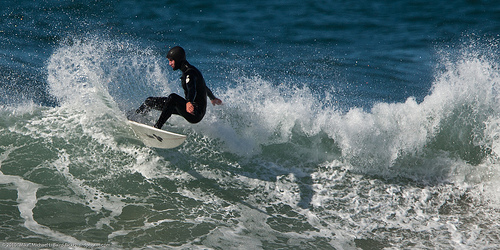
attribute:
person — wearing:
[120, 42, 240, 150]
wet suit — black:
[130, 48, 240, 140]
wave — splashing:
[206, 60, 496, 205]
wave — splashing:
[1, 32, 498, 248]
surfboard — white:
[113, 117, 193, 154]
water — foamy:
[1, 114, 498, 249]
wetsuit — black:
[135, 62, 217, 135]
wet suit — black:
[148, 63, 240, 140]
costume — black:
[179, 69, 192, 83]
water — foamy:
[342, 173, 459, 241]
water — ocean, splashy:
[7, 0, 498, 248]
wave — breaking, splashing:
[38, 30, 499, 175]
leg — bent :
[154, 92, 192, 129]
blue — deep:
[7, 8, 498, 45]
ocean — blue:
[8, 9, 492, 249]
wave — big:
[12, 40, 491, 231]